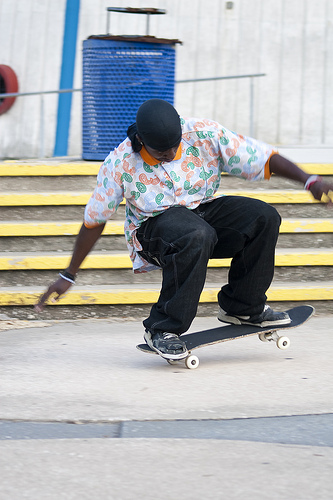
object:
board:
[134, 302, 316, 368]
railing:
[0, 72, 267, 98]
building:
[0, 0, 332, 162]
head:
[135, 99, 185, 165]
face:
[143, 143, 178, 166]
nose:
[167, 147, 175, 161]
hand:
[36, 272, 73, 314]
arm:
[69, 165, 116, 273]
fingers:
[52, 290, 63, 303]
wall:
[0, 0, 332, 161]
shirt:
[81, 118, 280, 274]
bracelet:
[59, 274, 78, 287]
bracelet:
[304, 174, 321, 193]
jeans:
[137, 194, 284, 334]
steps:
[0, 281, 332, 321]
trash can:
[81, 32, 182, 163]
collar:
[171, 139, 183, 161]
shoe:
[214, 305, 292, 329]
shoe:
[143, 328, 189, 361]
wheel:
[275, 336, 291, 353]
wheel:
[184, 352, 200, 370]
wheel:
[258, 328, 278, 344]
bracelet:
[300, 174, 319, 190]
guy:
[35, 98, 333, 362]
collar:
[138, 149, 162, 167]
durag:
[126, 98, 182, 157]